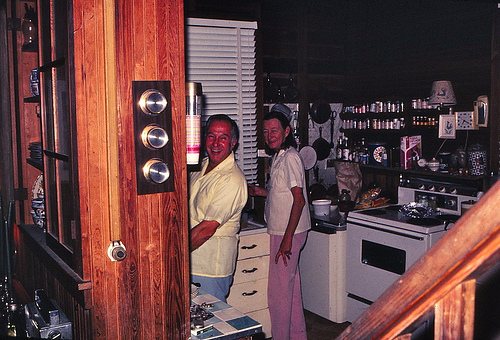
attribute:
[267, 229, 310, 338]
pants — pink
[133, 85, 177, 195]
clocks — round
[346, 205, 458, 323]
stove — white, black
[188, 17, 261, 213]
blinds — white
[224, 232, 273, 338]
cabinets — colored, wooden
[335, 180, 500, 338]
bannister — wooden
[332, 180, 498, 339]
rail — wooden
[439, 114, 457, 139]
picture — white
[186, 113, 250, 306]
guy — smiling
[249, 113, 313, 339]
woman — smiling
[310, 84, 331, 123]
pans — hanging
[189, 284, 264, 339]
tiles — blue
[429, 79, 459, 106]
lampshade — white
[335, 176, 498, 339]
railing — wooden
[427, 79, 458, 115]
lamp — white